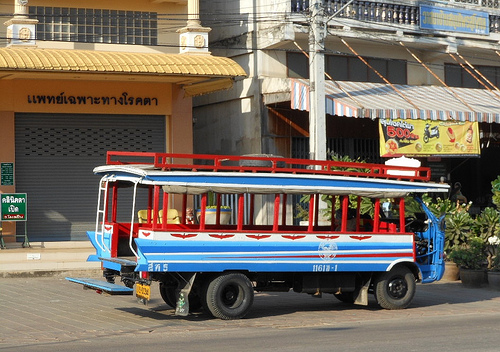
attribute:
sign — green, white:
[0, 189, 26, 224]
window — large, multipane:
[25, 4, 159, 44]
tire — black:
[203, 268, 255, 318]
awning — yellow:
[2, 44, 244, 97]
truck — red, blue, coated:
[168, 140, 473, 337]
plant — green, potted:
[433, 209, 499, 278]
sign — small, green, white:
[1, 192, 27, 224]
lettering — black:
[22, 88, 159, 109]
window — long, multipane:
[285, 40, 419, 85]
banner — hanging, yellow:
[373, 104, 483, 164]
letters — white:
[135, 238, 349, 272]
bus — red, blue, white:
[60, 147, 451, 317]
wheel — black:
[202, 268, 258, 324]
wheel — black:
[373, 268, 418, 309]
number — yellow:
[130, 286, 150, 298]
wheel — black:
[199, 274, 255, 321]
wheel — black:
[370, 270, 419, 304]